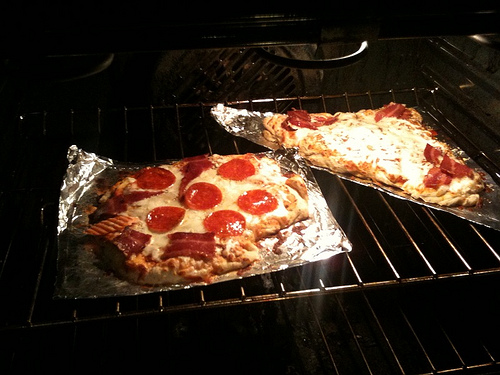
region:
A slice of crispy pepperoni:
[183, 180, 223, 210]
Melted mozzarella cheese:
[335, 125, 417, 175]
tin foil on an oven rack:
[265, 226, 411, 309]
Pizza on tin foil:
[65, 145, 372, 307]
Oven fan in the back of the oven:
[115, 50, 367, 102]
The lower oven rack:
[205, 305, 475, 370]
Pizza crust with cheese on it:
[131, 260, 214, 287]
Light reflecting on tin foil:
[293, 225, 345, 265]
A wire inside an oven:
[257, 37, 400, 72]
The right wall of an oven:
[428, 42, 498, 171]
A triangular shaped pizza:
[258, 90, 459, 200]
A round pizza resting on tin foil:
[90, 150, 326, 275]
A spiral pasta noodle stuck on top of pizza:
[77, 206, 147, 233]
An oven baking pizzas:
[36, 34, 490, 226]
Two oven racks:
[307, 268, 465, 357]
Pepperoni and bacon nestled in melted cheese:
[125, 197, 261, 255]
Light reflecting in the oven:
[297, 166, 367, 342]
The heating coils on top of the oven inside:
[226, 36, 382, 84]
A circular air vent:
[157, 53, 348, 168]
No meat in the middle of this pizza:
[322, 107, 430, 182]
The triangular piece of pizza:
[263, 101, 480, 218]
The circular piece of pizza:
[90, 148, 315, 298]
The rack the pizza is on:
[0, 84, 498, 337]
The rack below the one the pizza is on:
[0, 286, 494, 371]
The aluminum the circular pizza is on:
[55, 141, 356, 303]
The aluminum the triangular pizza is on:
[209, 99, 499, 234]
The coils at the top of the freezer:
[26, 35, 372, 91]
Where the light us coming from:
[227, 35, 362, 90]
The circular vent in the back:
[150, 47, 330, 128]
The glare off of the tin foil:
[296, 151, 352, 322]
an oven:
[8, 13, 495, 373]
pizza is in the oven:
[13, 9, 479, 373]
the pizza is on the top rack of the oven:
[18, 16, 491, 373]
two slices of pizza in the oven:
[46, 57, 499, 315]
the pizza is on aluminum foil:
[48, 73, 499, 313]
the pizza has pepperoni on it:
[58, 72, 482, 289]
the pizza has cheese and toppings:
[44, 68, 496, 288]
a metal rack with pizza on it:
[33, 91, 499, 310]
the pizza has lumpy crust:
[65, 93, 495, 296]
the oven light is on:
[46, 18, 480, 359]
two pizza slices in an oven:
[154, 99, 391, 269]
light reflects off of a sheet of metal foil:
[220, 148, 365, 278]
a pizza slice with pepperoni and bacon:
[59, 150, 309, 287]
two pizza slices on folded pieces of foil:
[98, 103, 368, 283]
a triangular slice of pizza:
[255, 99, 488, 229]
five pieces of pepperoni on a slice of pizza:
[120, 151, 300, 265]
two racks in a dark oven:
[354, 216, 489, 372]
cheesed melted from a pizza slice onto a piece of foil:
[245, 215, 332, 263]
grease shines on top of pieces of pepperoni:
[184, 182, 281, 239]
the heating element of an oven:
[240, 32, 403, 108]